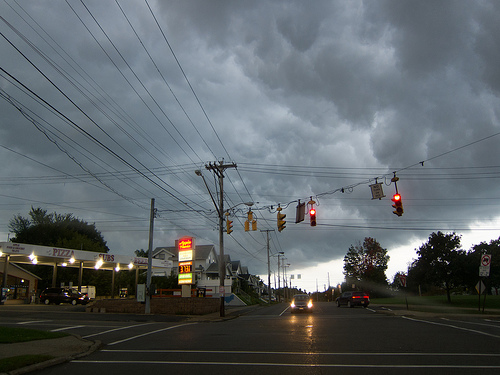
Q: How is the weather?
A: It is cloudy.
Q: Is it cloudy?
A: Yes, it is cloudy.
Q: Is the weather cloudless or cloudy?
A: It is cloudy.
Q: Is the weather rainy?
A: No, it is cloudy.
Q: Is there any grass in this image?
A: Yes, there is grass.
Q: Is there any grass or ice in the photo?
A: Yes, there is grass.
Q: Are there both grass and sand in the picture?
A: No, there is grass but no sand.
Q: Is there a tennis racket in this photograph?
A: No, there are no rackets.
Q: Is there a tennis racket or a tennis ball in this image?
A: No, there are no rackets or tennis balls.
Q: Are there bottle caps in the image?
A: No, there are no bottle caps.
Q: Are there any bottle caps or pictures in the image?
A: No, there are no bottle caps or pictures.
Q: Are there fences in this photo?
A: No, there are no fences.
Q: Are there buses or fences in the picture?
A: No, there are no fences or buses.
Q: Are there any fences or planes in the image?
A: No, there are no fences or planes.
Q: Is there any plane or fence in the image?
A: No, there are no fences or airplanes.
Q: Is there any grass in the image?
A: Yes, there is grass.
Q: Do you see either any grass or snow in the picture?
A: Yes, there is grass.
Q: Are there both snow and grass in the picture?
A: No, there is grass but no snow.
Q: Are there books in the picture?
A: No, there are no books.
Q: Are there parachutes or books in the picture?
A: No, there are no books or parachutes.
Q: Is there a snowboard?
A: No, there are no snowboards.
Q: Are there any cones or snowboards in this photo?
A: No, there are no snowboards or cones.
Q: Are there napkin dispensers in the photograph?
A: No, there are no napkin dispensers.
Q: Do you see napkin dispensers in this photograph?
A: No, there are no napkin dispensers.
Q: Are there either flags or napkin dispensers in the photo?
A: No, there are no napkin dispensers or flags.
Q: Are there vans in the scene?
A: No, there are no vans.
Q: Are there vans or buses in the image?
A: No, there are no vans or buses.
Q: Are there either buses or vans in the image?
A: No, there are no vans or buses.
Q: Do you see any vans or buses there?
A: No, there are no vans or buses.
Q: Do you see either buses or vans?
A: No, there are no vans or buses.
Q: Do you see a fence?
A: No, there are no fences.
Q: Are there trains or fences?
A: No, there are no fences or trains.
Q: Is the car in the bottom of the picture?
A: Yes, the car is in the bottom of the image.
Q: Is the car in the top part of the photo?
A: No, the car is in the bottom of the image.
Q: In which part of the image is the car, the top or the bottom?
A: The car is in the bottom of the image.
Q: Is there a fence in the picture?
A: No, there are no fences.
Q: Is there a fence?
A: No, there are no fences.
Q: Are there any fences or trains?
A: No, there are no fences or trains.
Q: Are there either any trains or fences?
A: No, there are no fences or trains.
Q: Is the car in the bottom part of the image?
A: Yes, the car is in the bottom of the image.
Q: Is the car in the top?
A: No, the car is in the bottom of the image.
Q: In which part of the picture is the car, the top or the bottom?
A: The car is in the bottom of the image.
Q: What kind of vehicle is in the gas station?
A: The vehicle is a car.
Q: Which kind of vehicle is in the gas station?
A: The vehicle is a car.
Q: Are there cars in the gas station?
A: Yes, there is a car in the gas station.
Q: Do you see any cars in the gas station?
A: Yes, there is a car in the gas station.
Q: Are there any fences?
A: No, there are no fences.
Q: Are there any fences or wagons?
A: No, there are no fences or wagons.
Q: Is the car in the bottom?
A: Yes, the car is in the bottom of the image.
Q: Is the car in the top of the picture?
A: No, the car is in the bottom of the image.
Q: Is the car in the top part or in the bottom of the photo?
A: The car is in the bottom of the image.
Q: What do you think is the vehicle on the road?
A: The vehicle is a car.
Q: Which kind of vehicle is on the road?
A: The vehicle is a car.